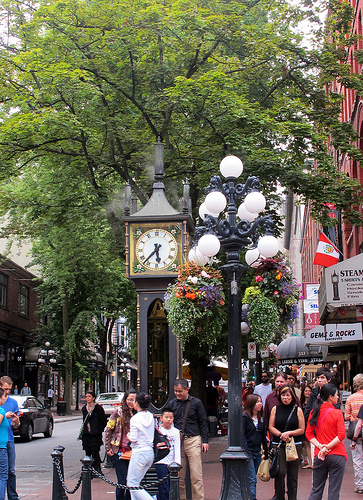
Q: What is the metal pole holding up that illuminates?
A: Lights.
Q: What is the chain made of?
A: Metal.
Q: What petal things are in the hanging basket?
A: Flowers.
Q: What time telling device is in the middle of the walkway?
A: Clock.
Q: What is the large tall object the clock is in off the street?
A: Tower.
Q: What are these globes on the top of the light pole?
A: Lights.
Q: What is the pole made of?
A: Metal.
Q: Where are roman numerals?
A: On clock.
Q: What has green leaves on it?
A: A large tree.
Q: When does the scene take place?
A: During the daytime.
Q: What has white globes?
A: Street lamp.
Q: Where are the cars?
A: On the road.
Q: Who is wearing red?
A: Woman with black ponytail.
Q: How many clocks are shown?
A: One.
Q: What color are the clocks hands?
A: Black.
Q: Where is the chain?
A: Foreground.